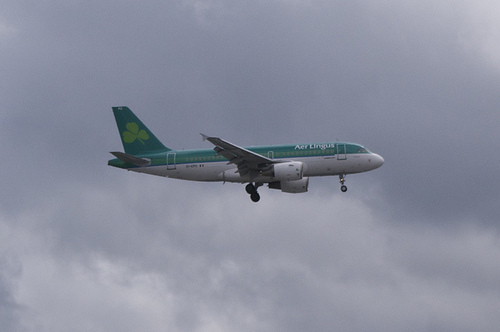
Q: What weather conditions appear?
A: It is cloudy.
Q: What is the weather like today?
A: It is cloudy.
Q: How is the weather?
A: It is cloudy.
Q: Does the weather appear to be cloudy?
A: Yes, it is cloudy.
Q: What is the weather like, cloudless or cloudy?
A: It is cloudy.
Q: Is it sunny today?
A: No, it is cloudy.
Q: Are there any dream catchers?
A: No, there are no dream catchers.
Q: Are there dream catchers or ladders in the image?
A: No, there are no dream catchers or ladders.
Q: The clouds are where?
A: The clouds are in the sky.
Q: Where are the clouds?
A: The clouds are in the sky.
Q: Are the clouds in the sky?
A: Yes, the clouds are in the sky.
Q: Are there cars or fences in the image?
A: No, there are no fences or cars.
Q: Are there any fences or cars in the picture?
A: No, there are no fences or cars.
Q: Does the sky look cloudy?
A: Yes, the sky is cloudy.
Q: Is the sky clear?
A: No, the sky is cloudy.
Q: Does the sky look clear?
A: No, the sky is cloudy.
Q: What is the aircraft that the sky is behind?
A: The aircraft is an airplane.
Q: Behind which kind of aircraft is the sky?
A: The sky is behind the airplane.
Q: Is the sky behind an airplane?
A: Yes, the sky is behind an airplane.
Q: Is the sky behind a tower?
A: No, the sky is behind an airplane.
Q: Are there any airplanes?
A: Yes, there is an airplane.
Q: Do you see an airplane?
A: Yes, there is an airplane.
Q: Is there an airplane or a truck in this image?
A: Yes, there is an airplane.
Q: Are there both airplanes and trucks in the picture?
A: No, there is an airplane but no trucks.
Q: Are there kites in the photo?
A: No, there are no kites.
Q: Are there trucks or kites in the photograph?
A: No, there are no kites or trucks.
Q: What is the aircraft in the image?
A: The aircraft is an airplane.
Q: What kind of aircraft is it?
A: The aircraft is an airplane.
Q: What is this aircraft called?
A: This is an airplane.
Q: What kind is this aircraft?
A: This is an airplane.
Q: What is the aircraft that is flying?
A: The aircraft is an airplane.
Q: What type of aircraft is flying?
A: The aircraft is an airplane.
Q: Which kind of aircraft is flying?
A: The aircraft is an airplane.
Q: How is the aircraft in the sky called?
A: The aircraft is an airplane.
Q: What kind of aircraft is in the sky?
A: The aircraft is an airplane.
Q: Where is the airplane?
A: The airplane is in the sky.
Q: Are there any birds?
A: No, there are no birds.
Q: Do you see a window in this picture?
A: Yes, there are windows.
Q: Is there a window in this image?
A: Yes, there are windows.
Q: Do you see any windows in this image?
A: Yes, there are windows.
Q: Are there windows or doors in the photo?
A: Yes, there are windows.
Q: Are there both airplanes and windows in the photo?
A: Yes, there are both windows and an airplane.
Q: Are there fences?
A: No, there are no fences.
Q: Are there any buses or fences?
A: No, there are no fences or buses.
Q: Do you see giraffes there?
A: No, there are no giraffes.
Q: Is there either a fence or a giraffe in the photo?
A: No, there are no giraffes or fences.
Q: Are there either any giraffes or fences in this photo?
A: No, there are no giraffes or fences.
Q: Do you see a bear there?
A: No, there are no bears.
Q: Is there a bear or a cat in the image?
A: No, there are no bears or cats.